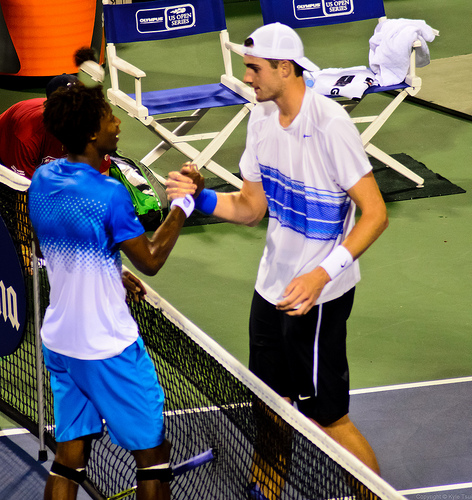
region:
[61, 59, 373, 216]
two people shaking hands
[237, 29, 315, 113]
man in white cap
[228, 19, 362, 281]
man in blue and white shirt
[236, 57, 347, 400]
man in black shorts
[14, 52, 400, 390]
three people by a tennis net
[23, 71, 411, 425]
three people on a tennis court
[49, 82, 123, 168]
person with black hair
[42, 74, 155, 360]
person in blue and white top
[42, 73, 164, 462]
person in blue shorts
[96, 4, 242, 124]
blue and white chair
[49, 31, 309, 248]
two men holding hands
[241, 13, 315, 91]
a man wearing a hat backwards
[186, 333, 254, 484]
a black and white tennis net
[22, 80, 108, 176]
a man with black hair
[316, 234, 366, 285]
a man wearing a white wrist band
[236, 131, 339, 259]
a man wearing a blue and white shirt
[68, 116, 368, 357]
two men wearing blue and white shirts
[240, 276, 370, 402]
a man wearing black shorts with a white stripe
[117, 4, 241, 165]
a folding chair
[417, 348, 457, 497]
white lines on a tennis court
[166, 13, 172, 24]
White letter on chair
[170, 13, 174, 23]
White letter on chair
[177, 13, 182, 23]
White letter on chair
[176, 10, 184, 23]
White letter on chair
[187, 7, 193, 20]
White letter on chair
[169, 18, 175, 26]
White letter on chair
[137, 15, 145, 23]
White letter on chair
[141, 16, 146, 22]
White letter on chair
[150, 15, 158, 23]
White letter on chair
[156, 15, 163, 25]
White letter on chair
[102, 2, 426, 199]
two chairs side by side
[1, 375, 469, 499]
blue surface of court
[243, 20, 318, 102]
white cap turned backwards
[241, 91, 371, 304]
white shirt with blue design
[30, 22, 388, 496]
two players shaking hands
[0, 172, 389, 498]
net with black string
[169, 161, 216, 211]
clasped hands with wrist bands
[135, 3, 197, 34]
white emblem on blue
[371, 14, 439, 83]
cloth over arm of chair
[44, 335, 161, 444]
blue shorts with pocket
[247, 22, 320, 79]
white hat on player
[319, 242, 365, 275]
white wrist cover on player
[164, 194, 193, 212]
white wrist cover on player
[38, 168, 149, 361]
blue and white shirt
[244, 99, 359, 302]
white and blue shirt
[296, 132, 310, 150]
blue nike logo on shirt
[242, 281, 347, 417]
blue shorts on player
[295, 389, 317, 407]
white nike logo on shorts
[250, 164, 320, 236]
blue and white stripes on shirt